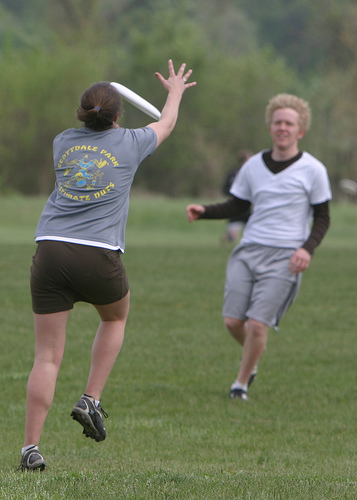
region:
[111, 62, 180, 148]
People playing with frisbee.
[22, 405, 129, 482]
Person wearing dark tennis shoes.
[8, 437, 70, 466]
Person wearing low cut socks.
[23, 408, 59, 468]
Person's socks are white.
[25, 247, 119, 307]
Person wearing dark shorts.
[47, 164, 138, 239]
Person wearing gray shirt.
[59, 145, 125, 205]
Yellow writing on person's shirt.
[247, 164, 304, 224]
Person wearing white v-neck shirt.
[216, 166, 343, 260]
Person wearing black long sleeved shirt.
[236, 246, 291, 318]
Person wearing gray shorts.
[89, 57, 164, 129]
White frisbee in the air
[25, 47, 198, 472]
Woman catching the frisbee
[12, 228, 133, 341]
Brown shorts on the woman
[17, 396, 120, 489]
Dirty black and white sneakers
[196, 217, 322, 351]
Black and grey shorts on the man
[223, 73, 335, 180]
man with curly blonde hair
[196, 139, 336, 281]
Black undershirt under the mans white shirt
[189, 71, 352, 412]
Man smiling at woman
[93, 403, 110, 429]
Black shoelaces on womans shos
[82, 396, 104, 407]
White socks on woman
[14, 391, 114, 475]
Woman is wearing shoes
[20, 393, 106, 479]
Woman is wearing black and white shoes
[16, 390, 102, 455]
Woman is wearing socks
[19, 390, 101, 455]
Woman is wearing white socks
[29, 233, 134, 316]
Woman is wearing shorts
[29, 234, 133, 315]
Woman is wearing black shorts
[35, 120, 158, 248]
Woman is wearing a shirt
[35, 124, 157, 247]
Woman is wearing a dark gray shirt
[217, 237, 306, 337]
Man is wearing shorts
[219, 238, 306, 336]
Man is wearing gray shorts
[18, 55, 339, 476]
two people playing frisbee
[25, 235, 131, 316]
brown shirt the woman is wearing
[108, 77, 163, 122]
a white frisbee the woman is using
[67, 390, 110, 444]
a soccer shoe the woman is wearing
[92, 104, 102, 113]
a band the woman used to ponytail her hair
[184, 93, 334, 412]
a boy in the field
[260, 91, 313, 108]
hair of the guy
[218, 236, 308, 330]
shorts the guy is wearing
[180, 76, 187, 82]
a ring on the finger of the woman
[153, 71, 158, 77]
a painted fingernail of the woman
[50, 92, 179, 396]
woman playing frisbee on field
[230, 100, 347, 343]
man playing frisbee on field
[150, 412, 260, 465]
green grass on field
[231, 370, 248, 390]
white socks on man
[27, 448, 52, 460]
white socks on woman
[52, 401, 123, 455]
black cleats on woman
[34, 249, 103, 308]
short shorts on woman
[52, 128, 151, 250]
gray shirt on woman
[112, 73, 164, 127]
white frisbee in mid air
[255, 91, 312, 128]
blonde hair on man